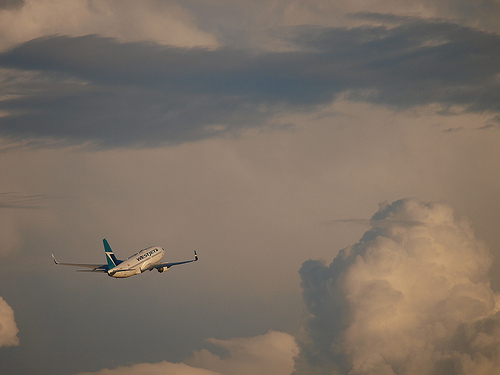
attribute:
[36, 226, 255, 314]
plane — white, airborne, flight, alone, air, wing, fin, window, red mark, commercial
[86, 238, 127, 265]
tail — blue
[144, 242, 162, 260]
letter — blue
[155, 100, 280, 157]
sky — cloud, darkened, ominous, grey, hazy, blue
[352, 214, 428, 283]
cloud — big, fluffy, white, whie, backside, high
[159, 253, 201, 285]
wing — white, blue, tip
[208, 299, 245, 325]
wind — white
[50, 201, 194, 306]
side — airline, black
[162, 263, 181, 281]
engine — jet